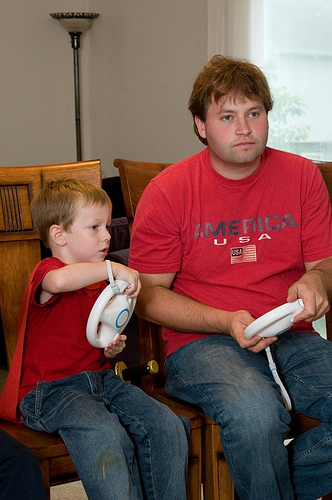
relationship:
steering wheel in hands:
[87, 278, 144, 361] [112, 262, 141, 296]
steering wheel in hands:
[87, 278, 144, 361] [103, 332, 128, 360]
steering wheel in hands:
[239, 293, 303, 344] [222, 308, 275, 352]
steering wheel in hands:
[239, 293, 303, 344] [285, 269, 330, 326]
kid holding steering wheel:
[16, 173, 189, 498] [85, 278, 138, 350]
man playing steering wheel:
[126, 53, 330, 498] [85, 278, 138, 350]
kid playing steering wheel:
[5, 171, 176, 488] [85, 278, 138, 350]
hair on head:
[185, 53, 273, 104] [191, 54, 270, 165]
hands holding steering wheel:
[217, 271, 330, 351] [239, 294, 316, 346]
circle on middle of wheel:
[113, 307, 130, 326] [83, 275, 137, 348]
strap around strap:
[103, 259, 119, 285] [104, 258, 116, 285]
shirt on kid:
[11, 253, 135, 436] [8, 172, 192, 498]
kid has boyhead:
[16, 173, 189, 498] [30, 178, 113, 264]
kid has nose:
[16, 173, 189, 498] [98, 226, 112, 241]